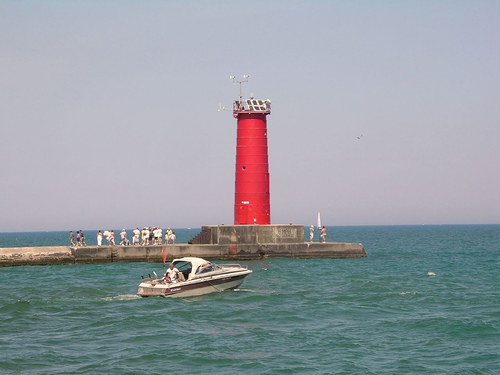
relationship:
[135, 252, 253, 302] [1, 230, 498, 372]
boat on water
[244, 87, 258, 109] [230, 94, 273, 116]
person walking on deck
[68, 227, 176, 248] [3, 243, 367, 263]
people stand on path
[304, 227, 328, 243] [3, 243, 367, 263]
people stand on path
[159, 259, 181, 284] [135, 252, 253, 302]
person rides in a boat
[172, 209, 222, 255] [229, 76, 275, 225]
stair lead up to lighthouse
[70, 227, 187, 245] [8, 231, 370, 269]
people standing on pier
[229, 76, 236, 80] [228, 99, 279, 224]
lamps are on top of tower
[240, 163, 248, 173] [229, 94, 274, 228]
hole on side of tower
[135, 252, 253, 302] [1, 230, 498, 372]
boat in water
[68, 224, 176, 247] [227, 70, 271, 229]
people standing around lighthouse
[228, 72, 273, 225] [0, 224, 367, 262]
lighthouse on a dock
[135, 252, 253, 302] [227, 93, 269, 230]
boat near lighthouse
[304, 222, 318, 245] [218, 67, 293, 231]
people in front of lighthouse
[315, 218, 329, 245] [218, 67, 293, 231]
people in front of lighthouse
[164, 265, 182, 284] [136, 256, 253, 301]
couple in a boat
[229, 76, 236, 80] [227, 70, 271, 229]
lamps on a lighthouse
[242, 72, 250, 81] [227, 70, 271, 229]
light on a lighthouse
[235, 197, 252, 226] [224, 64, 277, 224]
door on lighthouse